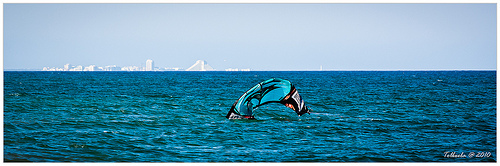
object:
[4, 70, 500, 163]
water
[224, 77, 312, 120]
pattern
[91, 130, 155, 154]
wave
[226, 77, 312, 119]
kite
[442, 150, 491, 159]
letter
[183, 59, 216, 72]
building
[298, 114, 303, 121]
stringedge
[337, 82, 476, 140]
waves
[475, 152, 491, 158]
number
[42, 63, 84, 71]
buildings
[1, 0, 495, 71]
sky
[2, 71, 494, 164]
ocean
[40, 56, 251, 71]
white print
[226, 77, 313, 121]
base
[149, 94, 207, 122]
wavy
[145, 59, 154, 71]
building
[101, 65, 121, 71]
building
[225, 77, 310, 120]
parachute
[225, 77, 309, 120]
sail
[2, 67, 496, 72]
horizon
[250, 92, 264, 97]
black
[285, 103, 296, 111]
orange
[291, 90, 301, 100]
white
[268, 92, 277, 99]
blue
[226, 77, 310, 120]
parasail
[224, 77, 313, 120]
sport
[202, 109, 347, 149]
landing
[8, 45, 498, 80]
distance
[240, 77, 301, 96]
top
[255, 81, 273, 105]
markings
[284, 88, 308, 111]
print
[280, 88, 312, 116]
letter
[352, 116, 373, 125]
bad sentence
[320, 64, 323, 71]
building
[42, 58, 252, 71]
city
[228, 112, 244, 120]
corner